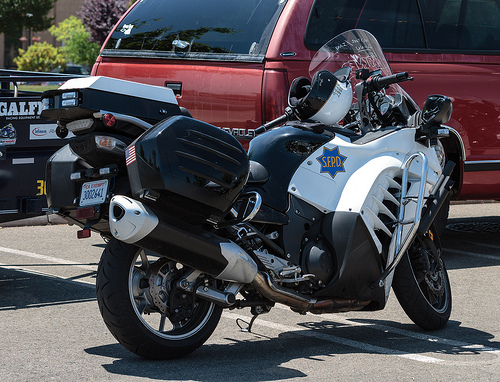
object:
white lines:
[383, 323, 479, 366]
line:
[2, 247, 494, 366]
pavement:
[0, 211, 498, 378]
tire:
[92, 226, 230, 361]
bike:
[41, 28, 467, 361]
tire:
[377, 230, 454, 331]